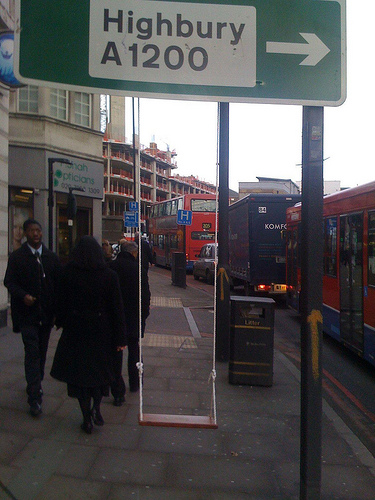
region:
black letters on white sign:
[93, 9, 256, 82]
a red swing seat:
[137, 400, 234, 441]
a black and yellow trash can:
[222, 288, 291, 400]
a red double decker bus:
[142, 177, 217, 287]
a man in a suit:
[4, 209, 73, 429]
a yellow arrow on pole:
[210, 262, 234, 328]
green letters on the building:
[44, 154, 101, 201]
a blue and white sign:
[171, 204, 194, 225]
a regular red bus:
[284, 177, 374, 358]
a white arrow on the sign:
[262, 24, 341, 93]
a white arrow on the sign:
[265, 31, 328, 64]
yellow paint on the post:
[306, 308, 320, 380]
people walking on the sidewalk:
[14, 221, 146, 431]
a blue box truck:
[227, 195, 291, 291]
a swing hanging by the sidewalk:
[130, 98, 223, 430]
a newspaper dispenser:
[227, 294, 277, 388]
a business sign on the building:
[46, 152, 103, 197]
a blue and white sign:
[177, 209, 192, 224]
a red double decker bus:
[144, 194, 213, 268]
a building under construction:
[107, 138, 213, 214]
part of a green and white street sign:
[10, 0, 350, 117]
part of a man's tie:
[32, 245, 41, 261]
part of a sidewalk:
[2, 257, 372, 497]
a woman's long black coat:
[50, 256, 131, 391]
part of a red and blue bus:
[280, 181, 373, 362]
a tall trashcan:
[224, 293, 281, 388]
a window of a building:
[42, 87, 70, 119]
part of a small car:
[190, 239, 221, 284]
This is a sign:
[98, 6, 270, 89]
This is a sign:
[49, 150, 105, 200]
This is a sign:
[178, 199, 198, 231]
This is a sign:
[118, 197, 138, 224]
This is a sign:
[244, 215, 299, 240]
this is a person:
[8, 206, 60, 421]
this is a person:
[56, 210, 131, 437]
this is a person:
[110, 229, 172, 415]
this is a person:
[95, 223, 140, 408]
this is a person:
[123, 221, 169, 352]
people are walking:
[15, 214, 151, 424]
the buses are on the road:
[147, 191, 367, 346]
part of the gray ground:
[6, 447, 63, 494]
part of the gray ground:
[85, 450, 151, 491]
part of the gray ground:
[156, 450, 210, 495]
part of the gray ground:
[225, 450, 285, 495]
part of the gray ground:
[236, 398, 276, 440]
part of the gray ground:
[326, 435, 350, 490]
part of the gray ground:
[277, 353, 292, 379]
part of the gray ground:
[218, 488, 294, 496]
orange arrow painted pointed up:
[290, 298, 332, 402]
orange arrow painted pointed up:
[300, 298, 328, 395]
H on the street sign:
[176, 209, 191, 224]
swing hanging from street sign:
[128, 84, 229, 430]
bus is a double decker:
[146, 187, 221, 273]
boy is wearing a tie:
[25, 240, 46, 269]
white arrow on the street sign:
[263, 30, 330, 70]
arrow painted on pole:
[210, 264, 231, 306]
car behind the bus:
[194, 242, 221, 280]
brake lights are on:
[257, 280, 294, 295]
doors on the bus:
[330, 210, 373, 368]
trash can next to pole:
[221, 291, 276, 387]